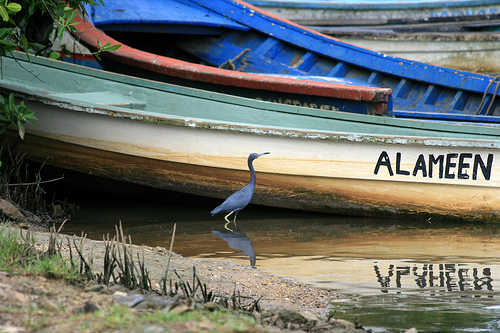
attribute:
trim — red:
[61, 5, 390, 111]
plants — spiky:
[6, 211, 268, 319]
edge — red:
[157, 69, 399, 101]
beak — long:
[256, 142, 271, 162]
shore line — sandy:
[0, 287, 332, 320]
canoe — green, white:
[72, 45, 489, 222]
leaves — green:
[0, 0, 119, 139]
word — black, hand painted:
[368, 147, 496, 187]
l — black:
[394, 151, 411, 176]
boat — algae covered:
[0, 0, 498, 222]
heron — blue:
[210, 139, 268, 259]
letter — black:
[473, 155, 492, 181]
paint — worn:
[310, 134, 496, 146]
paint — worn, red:
[142, 41, 384, 106]